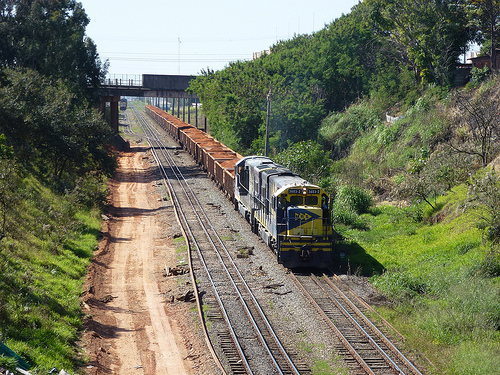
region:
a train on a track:
[133, 125, 371, 372]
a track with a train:
[100, 50, 354, 369]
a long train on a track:
[79, 71, 474, 341]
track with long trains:
[114, 74, 379, 324]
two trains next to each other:
[162, 90, 342, 363]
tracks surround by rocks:
[91, 66, 393, 373]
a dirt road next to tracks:
[18, 85, 228, 372]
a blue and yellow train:
[160, 67, 388, 348]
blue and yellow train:
[222, 145, 402, 313]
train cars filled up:
[128, 68, 269, 210]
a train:
[207, 152, 385, 320]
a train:
[237, 112, 371, 273]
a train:
[178, 107, 260, 211]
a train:
[230, 197, 337, 294]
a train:
[177, 125, 321, 265]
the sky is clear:
[109, 13, 229, 70]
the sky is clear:
[76, 18, 334, 74]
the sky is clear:
[125, 18, 176, 55]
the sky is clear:
[109, 10, 181, 46]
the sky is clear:
[114, 16, 160, 31]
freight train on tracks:
[143, 80, 340, 289]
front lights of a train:
[300, 183, 310, 198]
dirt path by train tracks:
[121, 220, 174, 372]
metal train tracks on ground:
[205, 292, 388, 365]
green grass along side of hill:
[384, 210, 489, 285]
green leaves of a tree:
[230, 56, 350, 113]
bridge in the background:
[112, 75, 223, 121]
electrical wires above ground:
[122, 43, 225, 70]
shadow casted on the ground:
[72, 315, 135, 342]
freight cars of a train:
[198, 135, 230, 168]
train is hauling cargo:
[135, 97, 343, 284]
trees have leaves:
[201, 38, 444, 134]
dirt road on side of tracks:
[105, 128, 182, 374]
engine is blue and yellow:
[224, 146, 356, 270]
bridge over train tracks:
[76, 63, 237, 145]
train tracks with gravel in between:
[157, 227, 428, 372]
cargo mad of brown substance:
[137, 101, 257, 199]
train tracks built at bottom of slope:
[9, 63, 475, 358]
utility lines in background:
[43, 28, 368, 99]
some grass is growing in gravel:
[240, 296, 369, 373]